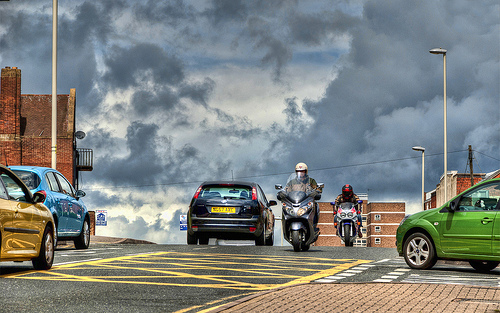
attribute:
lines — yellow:
[2, 233, 373, 303]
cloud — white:
[93, 39, 189, 91]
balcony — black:
[75, 129, 103, 181]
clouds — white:
[123, 65, 323, 129]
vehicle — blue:
[184, 164, 294, 256]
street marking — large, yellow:
[0, 247, 377, 312]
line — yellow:
[114, 244, 314, 301]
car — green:
[395, 179, 498, 271]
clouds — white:
[110, 31, 427, 181]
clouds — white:
[215, 68, 272, 110]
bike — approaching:
[328, 197, 365, 249]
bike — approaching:
[267, 169, 327, 255]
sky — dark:
[100, 9, 418, 156]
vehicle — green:
[395, 169, 499, 282]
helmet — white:
[293, 159, 308, 174]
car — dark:
[182, 174, 281, 252]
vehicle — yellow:
[0, 162, 57, 270]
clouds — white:
[291, 101, 476, 186]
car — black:
[184, 179, 274, 245]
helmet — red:
[341, 181, 354, 197]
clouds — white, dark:
[0, 0, 499, 245]